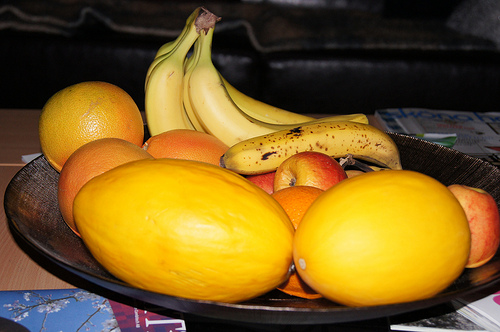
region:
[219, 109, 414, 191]
over ripe banana with dark spots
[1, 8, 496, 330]
plate of mixed fruit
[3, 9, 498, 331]
mixed fruit on a dark plate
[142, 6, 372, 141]
hand of yellow bananas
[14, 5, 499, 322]
pile of fruit on a brown plate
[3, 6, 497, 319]
fruit arranged on a dark colored plate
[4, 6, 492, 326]
fruit is stacked up on a brown plate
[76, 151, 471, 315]
pair of yellow melons on a plate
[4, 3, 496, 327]
fresh fruit on a plate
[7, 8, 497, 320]
fresh fruit piled on a brown plate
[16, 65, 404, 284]
this is a coffee table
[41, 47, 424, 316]
this is a bowl of fruit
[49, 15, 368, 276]
there are many different fruits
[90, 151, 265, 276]
this fruit is yellow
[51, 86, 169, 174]
this fruit is orange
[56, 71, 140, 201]
this is an orange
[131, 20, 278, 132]
this is a banana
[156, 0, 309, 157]
the banana is yellow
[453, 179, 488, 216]
this is an apple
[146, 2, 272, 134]
the bananas are in bunches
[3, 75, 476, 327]
a bowl of fruit on the table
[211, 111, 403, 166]
the banana is spotted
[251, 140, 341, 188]
an apple next to the banana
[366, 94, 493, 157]
a magazine on the table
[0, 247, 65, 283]
the table is tan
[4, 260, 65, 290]
the table is made of wood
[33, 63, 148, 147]
an orange next to the banana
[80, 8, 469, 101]
a couch in the background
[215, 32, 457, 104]
the couch is black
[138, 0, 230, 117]
the bananas are attached to each other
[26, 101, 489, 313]
fruit bowl on a table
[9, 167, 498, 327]
wooden bowl of fruit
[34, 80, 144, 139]
section of an orange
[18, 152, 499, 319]
brown fruit bowl on a table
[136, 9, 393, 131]
ripe bananas in a bunch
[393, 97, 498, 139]
magazines on the table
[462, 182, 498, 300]
part of an apple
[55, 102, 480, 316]
assorted fruit in a bowl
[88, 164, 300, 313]
yellow piece of food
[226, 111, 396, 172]
yellow food with brown spots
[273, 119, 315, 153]
brown spots on the banana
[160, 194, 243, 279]
light hitting the fruit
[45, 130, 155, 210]
reddish fruit in photo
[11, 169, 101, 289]
dark bowl in photo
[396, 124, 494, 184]
bowl holding the fruit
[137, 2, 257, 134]
group of bananas